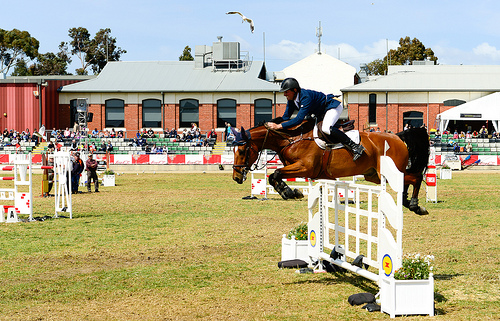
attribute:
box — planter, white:
[380, 247, 436, 316]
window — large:
[214, 98, 239, 132]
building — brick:
[62, 35, 289, 159]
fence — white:
[280, 154, 435, 316]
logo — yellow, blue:
[376, 249, 396, 279]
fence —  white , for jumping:
[251, 154, 310, 199]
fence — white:
[0, 150, 35, 220]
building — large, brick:
[354, 84, 444, 137]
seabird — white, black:
[228, 0, 261, 36]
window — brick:
[140, 97, 161, 127]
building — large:
[54, 40, 287, 141]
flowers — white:
[361, 234, 491, 312]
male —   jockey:
[269, 73, 364, 140]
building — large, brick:
[53, 90, 470, 145]